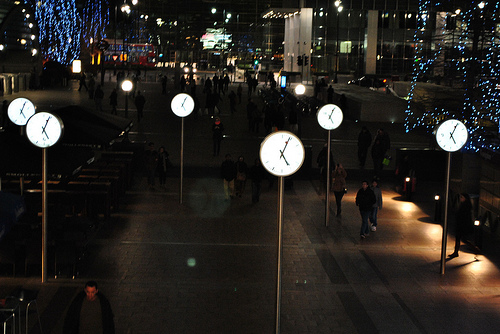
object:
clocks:
[6, 95, 39, 128]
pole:
[16, 124, 28, 201]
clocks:
[22, 111, 67, 151]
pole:
[38, 146, 49, 288]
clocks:
[168, 90, 197, 119]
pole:
[176, 117, 187, 204]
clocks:
[254, 129, 310, 180]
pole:
[270, 175, 284, 332]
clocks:
[312, 101, 345, 132]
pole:
[323, 131, 335, 230]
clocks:
[432, 117, 472, 155]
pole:
[437, 150, 453, 276]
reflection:
[184, 173, 235, 222]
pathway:
[90, 75, 327, 332]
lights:
[476, 0, 486, 10]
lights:
[119, 3, 133, 15]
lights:
[68, 38, 73, 44]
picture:
[0, 1, 499, 334]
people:
[350, 179, 380, 242]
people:
[369, 179, 388, 232]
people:
[221, 154, 238, 200]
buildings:
[262, 0, 499, 91]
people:
[327, 160, 352, 219]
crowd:
[175, 73, 242, 113]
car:
[346, 73, 395, 95]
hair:
[363, 181, 369, 186]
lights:
[305, 55, 310, 60]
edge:
[281, 175, 378, 333]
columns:
[297, 7, 316, 83]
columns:
[291, 13, 303, 79]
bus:
[96, 39, 163, 71]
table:
[19, 190, 111, 224]